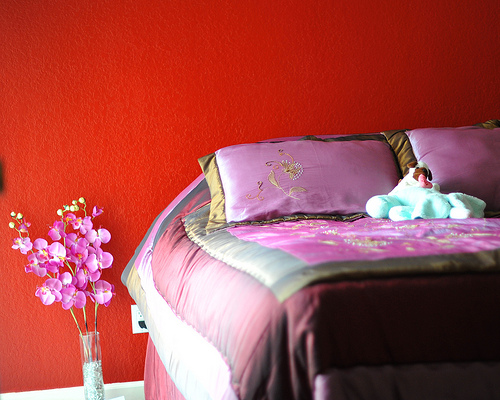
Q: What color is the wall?
A: Orange.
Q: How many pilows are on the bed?
A: Two.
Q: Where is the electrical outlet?
A: To the left of the bed near the baseboard.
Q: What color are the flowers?
A: Purple.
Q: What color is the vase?
A: Clear.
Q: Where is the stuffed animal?
A: On the bed.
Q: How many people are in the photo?
A: None.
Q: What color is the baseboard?
A: White.